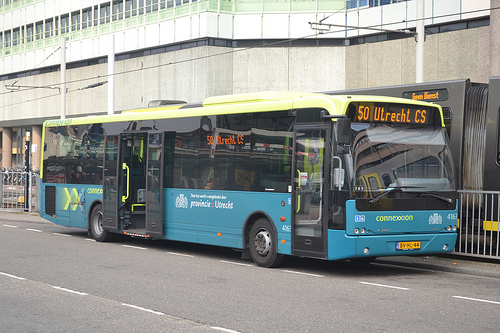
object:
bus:
[35, 91, 460, 270]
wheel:
[241, 216, 289, 266]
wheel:
[88, 200, 122, 243]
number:
[352, 105, 366, 122]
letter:
[228, 203, 236, 211]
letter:
[373, 215, 382, 225]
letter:
[187, 201, 196, 210]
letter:
[414, 108, 422, 125]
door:
[142, 134, 163, 238]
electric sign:
[350, 102, 443, 130]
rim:
[251, 226, 274, 259]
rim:
[90, 209, 106, 234]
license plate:
[392, 242, 423, 252]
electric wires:
[0, 7, 499, 96]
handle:
[119, 160, 135, 206]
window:
[33, 18, 48, 35]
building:
[0, 0, 499, 237]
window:
[33, 21, 41, 40]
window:
[58, 15, 67, 30]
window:
[136, 1, 144, 9]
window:
[127, 8, 136, 18]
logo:
[424, 210, 443, 226]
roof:
[38, 92, 449, 134]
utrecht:
[373, 102, 413, 128]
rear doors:
[99, 128, 122, 233]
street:
[0, 211, 499, 332]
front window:
[350, 122, 460, 211]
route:
[371, 103, 430, 127]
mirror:
[332, 167, 344, 188]